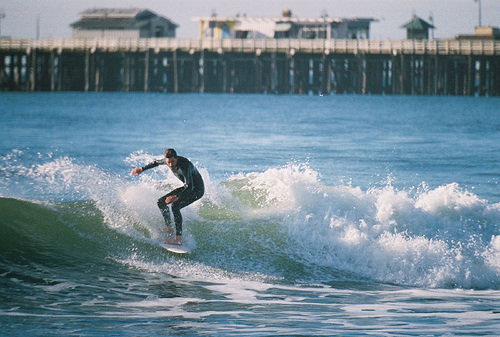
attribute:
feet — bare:
[153, 221, 185, 243]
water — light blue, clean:
[0, 86, 498, 335]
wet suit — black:
[139, 155, 204, 237]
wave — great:
[12, 190, 137, 272]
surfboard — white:
[138, 206, 193, 256]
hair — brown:
[162, 147, 181, 168]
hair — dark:
[161, 147, 178, 163]